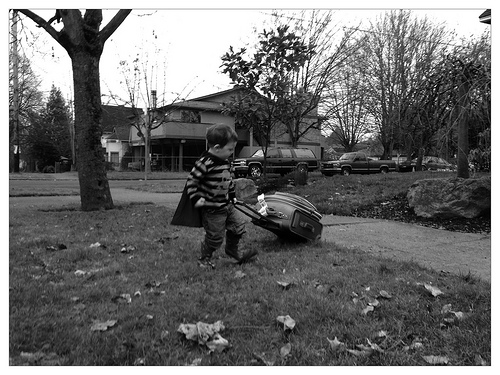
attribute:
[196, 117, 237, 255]
boy — dragging, little, pulling, holding, standing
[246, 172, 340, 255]
trolley — dragged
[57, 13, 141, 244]
tree — bare, leafless, brown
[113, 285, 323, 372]
leaves — brown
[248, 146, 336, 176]
wagon — parked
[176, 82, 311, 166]
house — big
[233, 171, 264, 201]
bag — hidden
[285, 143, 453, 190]
cars — parked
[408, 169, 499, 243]
rock — large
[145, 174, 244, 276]
cape — worn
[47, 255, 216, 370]
grass — here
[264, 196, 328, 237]
suitcase — pulled, held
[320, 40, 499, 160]
trees — standing